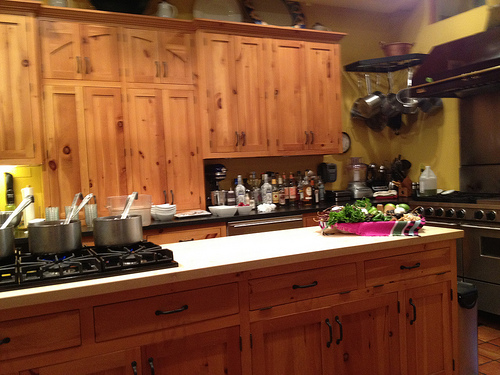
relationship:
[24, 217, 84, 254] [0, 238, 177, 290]
pot on stove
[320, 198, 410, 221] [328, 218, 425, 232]
vegetables in basket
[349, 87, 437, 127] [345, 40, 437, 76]
pots hanging from ceiling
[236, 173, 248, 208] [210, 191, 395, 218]
bottle on counter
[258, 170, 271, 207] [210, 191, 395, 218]
bottle on counter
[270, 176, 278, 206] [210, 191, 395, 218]
bottle on counter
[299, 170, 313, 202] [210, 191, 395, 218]
bottle on counter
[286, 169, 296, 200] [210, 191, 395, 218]
bottle on counter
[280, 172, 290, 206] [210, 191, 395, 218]
bottle on counter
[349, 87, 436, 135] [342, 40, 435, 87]
pots on rack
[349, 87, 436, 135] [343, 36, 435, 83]
pots hanging on rack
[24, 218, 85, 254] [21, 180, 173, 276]
pot on burner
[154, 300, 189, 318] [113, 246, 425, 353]
handle on cabinet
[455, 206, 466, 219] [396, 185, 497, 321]
knob on stove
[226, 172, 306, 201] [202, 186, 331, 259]
condiments on counter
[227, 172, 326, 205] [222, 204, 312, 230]
condiments on counter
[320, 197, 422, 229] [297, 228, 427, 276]
vegetables on counter